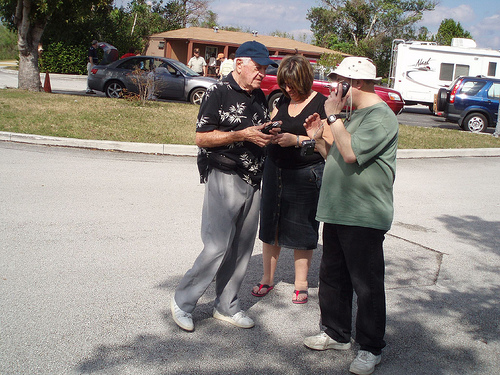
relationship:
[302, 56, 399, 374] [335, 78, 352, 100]
man talking on cellphone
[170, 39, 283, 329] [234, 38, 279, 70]
man wearing hat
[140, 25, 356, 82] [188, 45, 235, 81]
building behind people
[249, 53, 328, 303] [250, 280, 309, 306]
woman wearing sandals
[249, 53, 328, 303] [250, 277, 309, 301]
woman has feet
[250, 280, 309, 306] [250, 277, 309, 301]
sandals worn on feet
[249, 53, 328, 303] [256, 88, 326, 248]
woman wearing dress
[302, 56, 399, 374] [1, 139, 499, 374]
man standing on pavement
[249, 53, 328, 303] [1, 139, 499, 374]
woman standing on pavement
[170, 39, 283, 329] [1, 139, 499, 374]
man standing on pavement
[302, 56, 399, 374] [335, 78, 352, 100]
man holding cellphone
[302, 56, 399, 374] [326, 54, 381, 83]
man wearing hat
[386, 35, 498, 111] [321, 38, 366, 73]
rv beside tree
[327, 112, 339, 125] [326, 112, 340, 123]
watch around wrist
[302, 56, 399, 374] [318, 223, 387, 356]
man wearing pants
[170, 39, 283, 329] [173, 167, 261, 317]
man wearing pants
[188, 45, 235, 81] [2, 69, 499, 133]
people standing on pavement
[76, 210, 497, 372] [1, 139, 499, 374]
shadow cast on pavement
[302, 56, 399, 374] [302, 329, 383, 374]
man wearing shoes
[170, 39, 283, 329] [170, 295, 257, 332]
man wearing shoes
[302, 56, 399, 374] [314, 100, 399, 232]
man wearing shirt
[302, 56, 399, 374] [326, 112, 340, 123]
man has wrist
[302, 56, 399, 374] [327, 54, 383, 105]
man has head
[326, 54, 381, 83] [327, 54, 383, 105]
hat on top of head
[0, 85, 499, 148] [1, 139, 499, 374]
grass next to pavement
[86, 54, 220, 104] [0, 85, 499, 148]
car next to grass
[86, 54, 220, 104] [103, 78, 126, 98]
car has tire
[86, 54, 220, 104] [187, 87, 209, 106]
car has tire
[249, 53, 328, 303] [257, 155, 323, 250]
woman wearing skirt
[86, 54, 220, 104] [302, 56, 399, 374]
car parked behind man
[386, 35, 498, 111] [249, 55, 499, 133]
rv behind cars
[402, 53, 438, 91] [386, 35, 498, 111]
logo on side of rv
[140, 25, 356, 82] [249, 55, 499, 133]
building behind cars